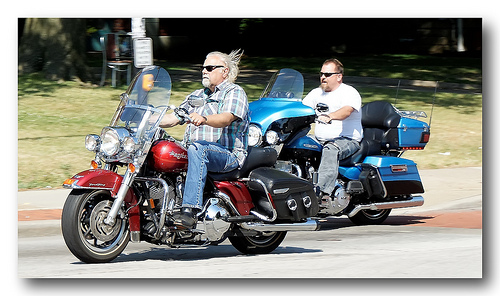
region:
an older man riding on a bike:
[157, 47, 252, 229]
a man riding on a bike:
[297, 56, 365, 208]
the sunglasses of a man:
[200, 62, 223, 70]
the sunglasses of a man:
[318, 70, 340, 79]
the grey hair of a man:
[205, 46, 243, 81]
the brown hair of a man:
[323, 59, 344, 74]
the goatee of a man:
[201, 75, 211, 85]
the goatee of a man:
[320, 81, 330, 90]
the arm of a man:
[190, 109, 230, 125]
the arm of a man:
[314, 100, 354, 122]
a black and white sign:
[135, 40, 156, 67]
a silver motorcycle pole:
[242, 218, 319, 230]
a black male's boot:
[161, 207, 203, 229]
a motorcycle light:
[98, 127, 125, 155]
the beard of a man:
[201, 73, 211, 88]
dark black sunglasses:
[197, 62, 227, 70]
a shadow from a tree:
[23, 76, 70, 96]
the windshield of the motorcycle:
[112, 65, 179, 129]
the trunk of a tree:
[20, 19, 96, 81]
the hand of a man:
[319, 112, 336, 128]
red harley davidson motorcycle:
[44, 63, 315, 243]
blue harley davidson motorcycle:
[238, 46, 443, 223]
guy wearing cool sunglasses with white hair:
[117, 37, 274, 183]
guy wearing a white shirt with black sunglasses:
[283, 31, 372, 187]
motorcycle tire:
[26, 170, 142, 272]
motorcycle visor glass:
[113, 58, 190, 156]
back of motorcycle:
[250, 147, 330, 224]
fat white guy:
[281, 50, 397, 194]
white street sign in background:
[128, 26, 170, 84]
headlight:
[72, 126, 137, 177]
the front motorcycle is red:
[59, 63, 319, 269]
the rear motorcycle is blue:
[238, 63, 438, 233]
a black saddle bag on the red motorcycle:
[248, 165, 319, 222]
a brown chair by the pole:
[93, 28, 132, 90]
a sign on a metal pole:
[130, 35, 156, 69]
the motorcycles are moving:
[55, 57, 437, 262]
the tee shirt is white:
[298, 80, 364, 145]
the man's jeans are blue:
[172, 136, 249, 207]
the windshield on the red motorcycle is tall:
[104, 64, 174, 160]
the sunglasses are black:
[195, 61, 230, 76]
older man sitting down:
[147, 41, 266, 256]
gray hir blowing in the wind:
[230, 48, 247, 64]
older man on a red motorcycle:
[56, 39, 316, 261]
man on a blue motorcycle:
[245, 38, 437, 237]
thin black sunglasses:
[312, 66, 341, 78]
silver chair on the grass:
[96, 25, 134, 91]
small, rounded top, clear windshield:
[97, 51, 175, 131]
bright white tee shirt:
[298, 76, 366, 139]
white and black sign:
[131, 36, 158, 67]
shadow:
[62, 241, 329, 262]